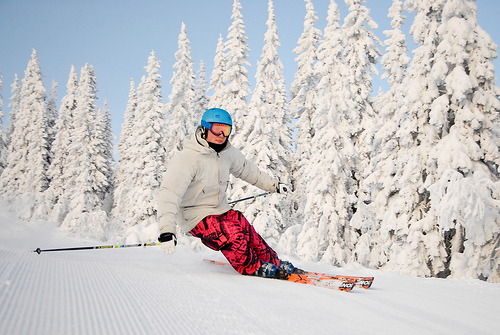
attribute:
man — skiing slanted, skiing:
[152, 95, 303, 285]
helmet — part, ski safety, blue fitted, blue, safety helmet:
[201, 105, 235, 125]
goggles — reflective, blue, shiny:
[207, 123, 234, 136]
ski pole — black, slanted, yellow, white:
[29, 229, 176, 256]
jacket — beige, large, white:
[153, 139, 278, 239]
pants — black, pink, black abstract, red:
[194, 206, 296, 282]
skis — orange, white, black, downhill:
[204, 253, 376, 295]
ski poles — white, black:
[32, 188, 294, 258]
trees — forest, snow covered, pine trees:
[1, 3, 495, 281]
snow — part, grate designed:
[0, 217, 498, 333]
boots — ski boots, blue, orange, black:
[258, 254, 296, 279]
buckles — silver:
[256, 260, 291, 272]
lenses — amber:
[214, 125, 230, 132]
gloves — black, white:
[157, 230, 179, 256]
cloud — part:
[44, 73, 69, 100]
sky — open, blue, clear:
[1, 5, 499, 142]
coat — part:
[156, 131, 311, 254]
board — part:
[255, 236, 464, 329]